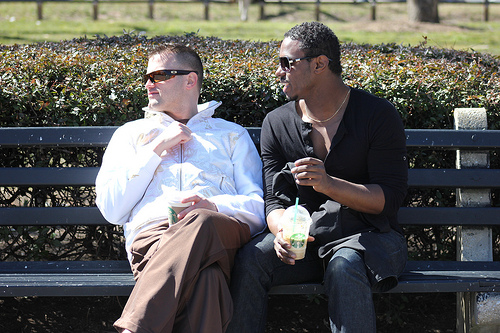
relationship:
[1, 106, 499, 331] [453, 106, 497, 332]
bench has pillar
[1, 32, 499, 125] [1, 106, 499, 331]
plants beside bench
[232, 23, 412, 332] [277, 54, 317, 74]
man wearing sunglasses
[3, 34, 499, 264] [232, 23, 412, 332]
bushes behind man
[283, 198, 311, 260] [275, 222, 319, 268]
cup in hand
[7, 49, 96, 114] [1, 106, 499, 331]
hedge behind bench